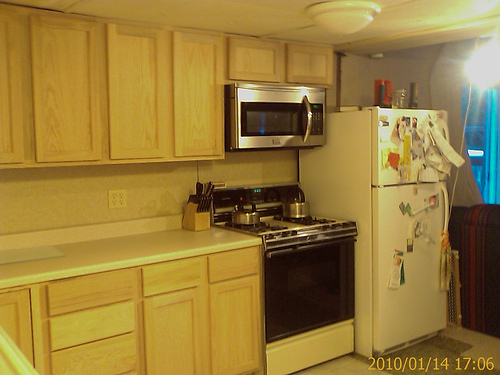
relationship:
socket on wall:
[108, 188, 127, 209] [2, 150, 301, 236]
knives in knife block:
[187, 181, 216, 214] [180, 201, 212, 232]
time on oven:
[252, 187, 264, 195] [207, 179, 358, 374]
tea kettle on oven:
[232, 198, 260, 225] [207, 179, 358, 374]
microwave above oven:
[225, 82, 327, 153] [207, 179, 358, 374]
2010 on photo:
[368, 356, 404, 374] [1, 0, 500, 372]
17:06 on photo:
[456, 356, 496, 374] [1, 0, 500, 372]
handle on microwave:
[301, 95, 313, 141] [225, 82, 327, 153]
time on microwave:
[312, 102, 320, 108] [225, 82, 327, 153]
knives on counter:
[187, 181, 216, 214] [1, 225, 263, 290]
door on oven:
[265, 234, 354, 344] [207, 179, 358, 374]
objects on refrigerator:
[376, 109, 453, 292] [297, 107, 450, 363]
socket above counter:
[108, 188, 127, 209] [1, 225, 263, 290]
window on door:
[246, 109, 300, 133] [225, 82, 327, 153]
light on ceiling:
[305, 1, 382, 32] [1, 0, 500, 57]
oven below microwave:
[207, 179, 358, 374] [225, 82, 327, 153]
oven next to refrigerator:
[207, 179, 358, 374] [297, 107, 450, 363]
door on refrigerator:
[372, 181, 451, 352] [297, 107, 450, 363]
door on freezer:
[373, 109, 451, 186] [299, 107, 451, 187]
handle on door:
[440, 186, 451, 238] [372, 181, 451, 352]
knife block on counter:
[180, 201, 212, 232] [1, 225, 263, 290]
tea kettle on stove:
[282, 185, 311, 218] [209, 180, 357, 374]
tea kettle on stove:
[232, 198, 260, 225] [209, 180, 357, 374]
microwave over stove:
[225, 82, 327, 153] [209, 180, 357, 374]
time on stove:
[252, 187, 264, 195] [209, 180, 357, 374]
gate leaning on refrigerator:
[446, 248, 464, 332] [297, 107, 450, 363]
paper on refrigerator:
[387, 252, 405, 289] [297, 107, 450, 363]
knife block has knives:
[180, 201, 212, 232] [187, 181, 216, 214]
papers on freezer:
[380, 110, 466, 181] [299, 107, 451, 187]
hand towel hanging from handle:
[440, 230, 454, 291] [440, 186, 451, 238]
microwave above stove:
[225, 82, 327, 153] [209, 180, 357, 374]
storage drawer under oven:
[265, 317, 354, 374] [207, 179, 358, 374]